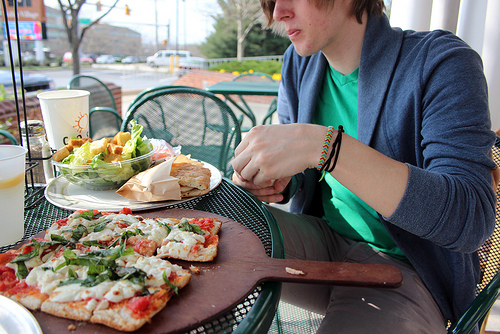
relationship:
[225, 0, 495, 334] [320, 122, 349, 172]
person has bracelets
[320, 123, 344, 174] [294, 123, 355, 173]
bracelet on wrist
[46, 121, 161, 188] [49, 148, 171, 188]
salad in bowl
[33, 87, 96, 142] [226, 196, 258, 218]
cup on table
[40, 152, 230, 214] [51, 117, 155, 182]
plate under salad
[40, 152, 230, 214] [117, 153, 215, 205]
plate under sandwich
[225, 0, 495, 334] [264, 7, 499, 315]
person wearing sweater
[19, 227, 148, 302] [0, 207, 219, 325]
green veggies on pizza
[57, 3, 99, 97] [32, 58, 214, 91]
tree next to road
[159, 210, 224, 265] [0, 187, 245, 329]
square slice of a pizza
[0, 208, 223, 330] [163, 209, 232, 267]
pizza next to pizza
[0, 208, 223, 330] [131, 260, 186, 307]
pizza by slice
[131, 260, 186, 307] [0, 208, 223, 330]
slice by pizza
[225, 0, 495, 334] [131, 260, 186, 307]
person eating slice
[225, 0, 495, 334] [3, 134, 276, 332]
person sitting at table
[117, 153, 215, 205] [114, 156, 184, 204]
sandwich in a bag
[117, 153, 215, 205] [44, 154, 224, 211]
sandwich on a plate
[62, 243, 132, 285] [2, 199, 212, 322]
spinach on pizza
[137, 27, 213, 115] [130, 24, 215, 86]
van on road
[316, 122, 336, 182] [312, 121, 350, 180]
bracelet around a wrist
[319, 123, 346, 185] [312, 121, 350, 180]
bracelet around a wrist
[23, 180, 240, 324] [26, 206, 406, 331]
pizza on a tray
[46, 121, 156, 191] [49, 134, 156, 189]
salad in a bowl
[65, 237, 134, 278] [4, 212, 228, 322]
green veggies on pizza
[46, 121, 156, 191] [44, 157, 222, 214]
salad on plate